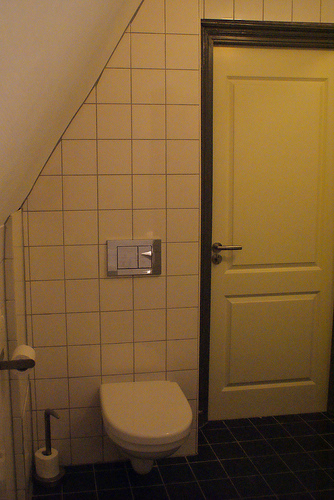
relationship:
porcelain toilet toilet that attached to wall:
[101, 356, 190, 500] [96, 331, 160, 338]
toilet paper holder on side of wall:
[9, 343, 36, 415] [15, 293, 47, 300]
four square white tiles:
[101, 327, 165, 376] [127, 328, 142, 356]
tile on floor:
[189, 459, 228, 481] [117, 471, 137, 500]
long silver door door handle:
[192, 229, 267, 276] [216, 242, 245, 252]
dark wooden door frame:
[204, 61, 213, 330] [197, 424, 204, 443]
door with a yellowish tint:
[216, 72, 327, 346] [260, 339, 287, 353]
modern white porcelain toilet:
[86, 343, 201, 455] [99, 376, 196, 477]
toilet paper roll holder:
[20, 387, 66, 488] [45, 410, 50, 445]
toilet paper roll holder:
[4, 311, 44, 416] [15, 358, 35, 367]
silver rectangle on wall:
[108, 238, 162, 278] [74, 214, 170, 324]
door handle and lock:
[203, 236, 246, 265] [207, 242, 219, 260]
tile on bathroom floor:
[122, 430, 315, 493] [244, 466, 267, 493]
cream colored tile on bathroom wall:
[37, 313, 196, 380] [91, 334, 109, 354]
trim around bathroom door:
[189, 307, 221, 438] [243, 293, 302, 414]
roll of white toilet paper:
[10, 334, 42, 384] [18, 352, 35, 369]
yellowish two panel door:
[257, 156, 310, 416] [264, 336, 277, 386]